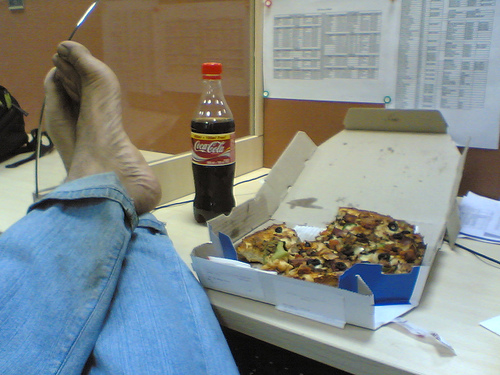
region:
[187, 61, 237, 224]
coke bottle sits on desk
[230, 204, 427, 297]
pizza sits in box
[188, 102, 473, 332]
box sits on desk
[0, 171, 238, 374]
jeans are worn by man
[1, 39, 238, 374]
man wears jeans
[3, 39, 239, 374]
man kicks feet up on desk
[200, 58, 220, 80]
lid is on bottle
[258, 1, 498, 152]
paper is attached to the wall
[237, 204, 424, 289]
someone has started to eat the pizza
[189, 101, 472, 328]
cardboard box is open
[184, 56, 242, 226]
A bottle of Coca Cola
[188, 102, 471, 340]
Pizza in an open box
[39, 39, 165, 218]
A pair of bare feet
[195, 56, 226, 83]
A red cap on a bottle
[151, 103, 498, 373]
Pizza box on a table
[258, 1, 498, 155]
Two white papers on the wall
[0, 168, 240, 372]
A pair of blue jeans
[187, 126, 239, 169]
A label on a bottle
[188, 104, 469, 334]
The pizza box is cardboard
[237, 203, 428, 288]
A slice is missing from the pizza pie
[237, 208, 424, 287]
A small combination pizza.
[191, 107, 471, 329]
A cardboard pizza box.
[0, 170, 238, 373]
A pair of jeans.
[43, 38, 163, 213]
A pair of feet.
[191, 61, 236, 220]
A full soda bottle.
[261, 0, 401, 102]
A white printed paper.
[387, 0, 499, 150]
A paper with black print.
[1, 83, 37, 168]
A black cloth object.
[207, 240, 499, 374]
A light wood desktop.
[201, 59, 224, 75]
Red soda bottle lid.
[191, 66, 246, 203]
a soda bottle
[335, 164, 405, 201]
a cardboard box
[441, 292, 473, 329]
the table is made of wood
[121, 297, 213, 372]
blue jeans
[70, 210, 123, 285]
dirt on the pants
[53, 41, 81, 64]
the persons toes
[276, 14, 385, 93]
paper on the wall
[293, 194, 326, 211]
a stain on the box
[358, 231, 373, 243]
a black olive on the pizza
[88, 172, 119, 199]
the pants are cuffed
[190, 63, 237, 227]
a bottle of soda on a desk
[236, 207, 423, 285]
slices of pizza in a box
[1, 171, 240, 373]
man wearing blue jeans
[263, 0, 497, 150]
papers tacked on a cork board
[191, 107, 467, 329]
a pizza box on a desk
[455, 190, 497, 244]
white papers on a desk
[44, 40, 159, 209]
bare feet propped on a desk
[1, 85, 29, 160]
a small black bag on a desk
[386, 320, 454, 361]
grease stain on a desk